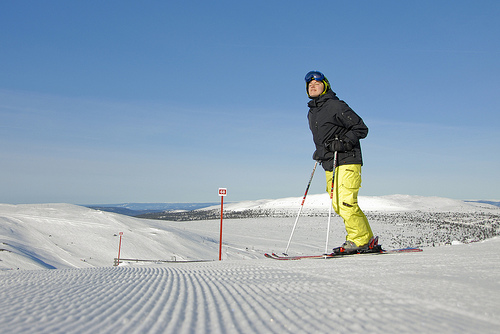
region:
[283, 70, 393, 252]
man in snow skiing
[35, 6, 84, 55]
white clouds against blue sky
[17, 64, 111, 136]
white clouds against blue sky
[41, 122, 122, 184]
white clouds against blue sky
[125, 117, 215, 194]
white clouds against blue sky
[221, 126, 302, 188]
white clouds against blue sky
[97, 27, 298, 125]
white clouds against blue sky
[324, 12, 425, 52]
white clouds against blue sky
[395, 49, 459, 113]
white clouds against blue sky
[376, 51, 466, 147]
white clouds against blue sky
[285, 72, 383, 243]
person cross country skiing in snow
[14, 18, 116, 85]
white clouds against blue sky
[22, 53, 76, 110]
white clouds against blue sky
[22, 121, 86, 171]
white clouds against blue sky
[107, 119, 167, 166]
white clouds against blue sky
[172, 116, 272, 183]
white clouds against blue sky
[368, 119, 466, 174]
white clouds against blue sky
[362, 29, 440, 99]
white clouds against blue sky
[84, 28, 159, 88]
white clouds against blue sky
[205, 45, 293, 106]
white clouds against blue sky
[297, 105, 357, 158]
man wearing black jacket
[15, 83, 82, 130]
white clouds against blue sky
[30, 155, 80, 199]
white clouds against blue sky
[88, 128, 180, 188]
white clouds against blue sky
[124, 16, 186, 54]
white clouds against blue sky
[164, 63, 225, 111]
white clouds against blue sky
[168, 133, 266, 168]
white clouds against blue sky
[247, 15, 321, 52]
white clouds against blue sky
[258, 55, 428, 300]
a woman skier on the snow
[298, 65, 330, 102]
a woman wearing ski goggles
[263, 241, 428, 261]
a pair of skis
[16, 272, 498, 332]
fresh white fluffy snow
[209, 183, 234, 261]
a red sign on a snowy hill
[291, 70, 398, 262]
a woman wearing a black jacket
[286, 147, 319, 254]
a white and red ski pole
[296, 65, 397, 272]
a woman wearing yellow ski pants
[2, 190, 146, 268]
a snowy hillside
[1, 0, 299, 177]
a clear blue sky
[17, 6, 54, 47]
white clouds against blue sky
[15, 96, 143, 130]
white clouds against blue sky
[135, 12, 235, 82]
white clouds against blue sky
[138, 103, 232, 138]
white clouds against blue sky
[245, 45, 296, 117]
white clouds against blue sky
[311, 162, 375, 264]
person wearing yellow pants